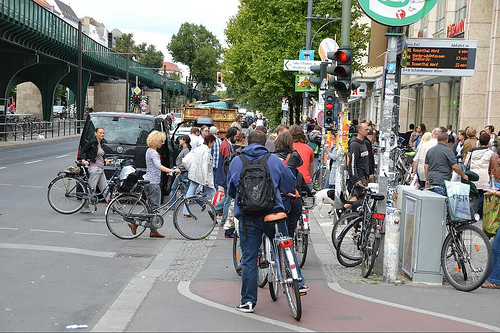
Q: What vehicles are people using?
A: Bicycles.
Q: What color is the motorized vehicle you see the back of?
A: Black.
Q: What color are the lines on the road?
A: White.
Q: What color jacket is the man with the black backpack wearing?
A: Blue.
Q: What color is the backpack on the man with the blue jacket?
A: Black.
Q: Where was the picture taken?
A: On a street.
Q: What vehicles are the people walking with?
A: Bicycles.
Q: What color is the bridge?
A: Green.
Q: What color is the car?
A: Black.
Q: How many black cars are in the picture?
A: 1.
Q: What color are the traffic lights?
A: Red.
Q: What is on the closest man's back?
A: Backpack.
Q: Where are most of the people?
A: The sidewalk.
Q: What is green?
A: Trees.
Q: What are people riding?
A: Bicycles.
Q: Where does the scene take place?
A: Near a city street.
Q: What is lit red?
A: Traffic lights.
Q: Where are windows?
A: On a van.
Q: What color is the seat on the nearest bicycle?
A: Tan.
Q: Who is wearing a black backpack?
A: The person in the blue jacket.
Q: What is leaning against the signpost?
A: A bicycle.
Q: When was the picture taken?
A: Daytime.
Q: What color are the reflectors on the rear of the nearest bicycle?
A: Red.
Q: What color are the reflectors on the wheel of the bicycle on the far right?
A: Orange.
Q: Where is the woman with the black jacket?
A: Near the black van.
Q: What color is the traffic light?
A: Red.